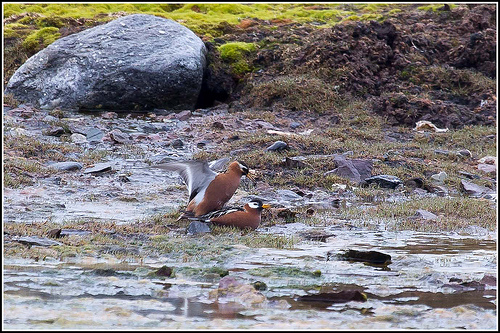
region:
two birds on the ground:
[165, 155, 313, 250]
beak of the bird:
[263, 198, 274, 216]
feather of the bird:
[157, 151, 217, 196]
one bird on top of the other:
[193, 142, 287, 220]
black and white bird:
[242, 192, 272, 223]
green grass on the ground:
[378, 198, 418, 220]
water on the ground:
[415, 234, 468, 266]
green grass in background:
[201, 6, 232, 30]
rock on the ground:
[18, 23, 198, 128]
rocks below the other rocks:
[106, 121, 166, 150]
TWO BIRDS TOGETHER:
[152, 152, 276, 244]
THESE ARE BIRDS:
[147, 155, 277, 232]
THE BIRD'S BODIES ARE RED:
[156, 151, 272, 241]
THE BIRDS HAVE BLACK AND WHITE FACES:
[238, 158, 265, 214]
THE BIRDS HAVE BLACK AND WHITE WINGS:
[148, 152, 243, 224]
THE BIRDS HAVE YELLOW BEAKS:
[243, 169, 270, 216]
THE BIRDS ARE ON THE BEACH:
[154, 151, 273, 236]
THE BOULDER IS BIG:
[3, 10, 208, 123]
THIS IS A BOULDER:
[5, 12, 208, 133]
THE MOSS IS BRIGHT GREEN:
[0, 2, 473, 106]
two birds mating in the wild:
[163, 148, 274, 248]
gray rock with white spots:
[13, 13, 210, 118]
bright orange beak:
[261, 202, 269, 208]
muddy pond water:
[13, 235, 488, 315]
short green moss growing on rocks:
[2, 5, 78, 37]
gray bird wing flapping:
[160, 153, 214, 193]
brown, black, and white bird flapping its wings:
[165, 149, 255, 202]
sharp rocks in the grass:
[332, 146, 497, 213]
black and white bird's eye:
[247, 200, 260, 207]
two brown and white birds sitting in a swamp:
[111, 145, 333, 242]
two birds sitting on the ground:
[153, 157, 275, 237]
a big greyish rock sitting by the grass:
[20, 12, 207, 107]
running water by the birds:
[16, 244, 496, 324]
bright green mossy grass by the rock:
[8, 9, 280, 39]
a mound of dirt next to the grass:
[313, 7, 492, 129]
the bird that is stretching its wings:
[148, 147, 265, 237]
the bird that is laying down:
[206, 193, 281, 231]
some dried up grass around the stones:
[342, 120, 442, 178]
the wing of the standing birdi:
[157, 156, 217, 194]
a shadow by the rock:
[180, 73, 227, 113]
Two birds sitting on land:
[127, 132, 277, 234]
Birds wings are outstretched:
[151, 135, 248, 210]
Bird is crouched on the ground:
[198, 200, 270, 230]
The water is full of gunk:
[216, 213, 383, 326]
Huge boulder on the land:
[17, 16, 214, 106]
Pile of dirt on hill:
[284, 30, 489, 110]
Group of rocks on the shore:
[234, 132, 438, 209]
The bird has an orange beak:
[257, 200, 270, 210]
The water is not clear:
[267, 265, 374, 318]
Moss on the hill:
[176, 7, 261, 28]